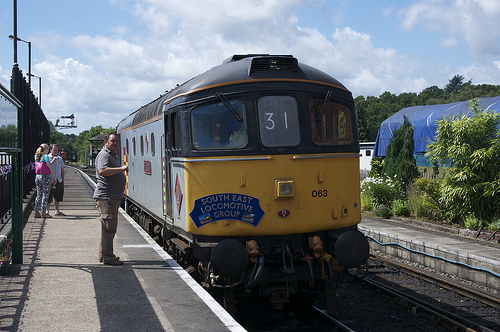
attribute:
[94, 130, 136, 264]
man — standing, adult, white, older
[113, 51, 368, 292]
train — yellow, black, silver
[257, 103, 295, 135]
number — 31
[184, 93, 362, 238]
front — yellow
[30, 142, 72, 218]
people — standing, waiting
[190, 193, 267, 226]
sign — blue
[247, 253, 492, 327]
tracks — train, train's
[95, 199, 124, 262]
pants — khaki, tan, cargo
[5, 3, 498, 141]
sky — blue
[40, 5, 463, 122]
clouds — white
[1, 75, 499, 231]
trees — green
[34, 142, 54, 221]
woman — talking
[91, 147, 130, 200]
shirt — grey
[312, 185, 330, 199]
number — 63, 063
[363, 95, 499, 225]
plants — white, green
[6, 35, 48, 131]
lights — street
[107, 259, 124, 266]
shoe — brown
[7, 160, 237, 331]
platform — train's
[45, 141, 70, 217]
man — talking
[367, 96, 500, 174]
structure — covered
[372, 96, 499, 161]
tarp — blue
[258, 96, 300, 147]
window — train's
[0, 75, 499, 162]
foilage — green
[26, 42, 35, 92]
pole — metal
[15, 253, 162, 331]
shadow — cast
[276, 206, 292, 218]
sensor — south east locomotiv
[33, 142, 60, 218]
girl — blond, teenage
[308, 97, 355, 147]
window — train's